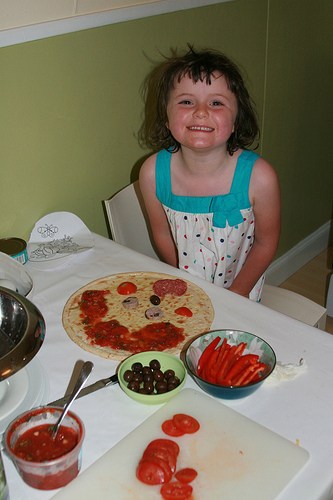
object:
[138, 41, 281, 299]
girl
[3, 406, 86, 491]
container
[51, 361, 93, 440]
spoon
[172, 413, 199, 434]
tomato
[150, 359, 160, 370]
olive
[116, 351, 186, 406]
bowl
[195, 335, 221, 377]
bell peppers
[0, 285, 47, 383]
colander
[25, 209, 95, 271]
paper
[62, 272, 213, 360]
pizza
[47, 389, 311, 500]
cutting board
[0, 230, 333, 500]
table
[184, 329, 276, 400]
bowl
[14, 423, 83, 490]
salsa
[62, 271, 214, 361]
dough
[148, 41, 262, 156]
hair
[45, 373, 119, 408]
knife